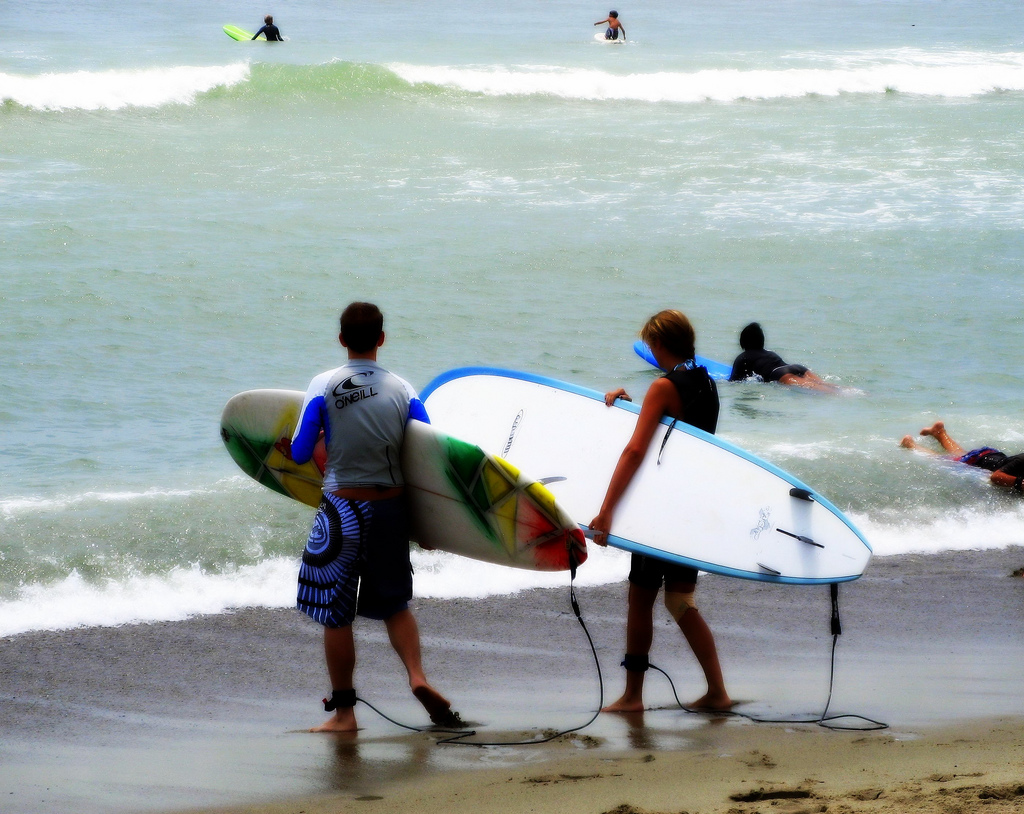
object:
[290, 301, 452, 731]
boy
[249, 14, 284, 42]
surfer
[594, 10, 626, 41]
boy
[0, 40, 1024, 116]
waves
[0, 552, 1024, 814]
sand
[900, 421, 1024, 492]
child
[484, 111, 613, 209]
water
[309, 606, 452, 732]
legs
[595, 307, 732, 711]
person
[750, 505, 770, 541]
steamer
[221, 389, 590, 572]
boat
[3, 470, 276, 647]
water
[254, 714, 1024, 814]
mud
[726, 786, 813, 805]
marks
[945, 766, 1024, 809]
marks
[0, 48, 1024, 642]
wavy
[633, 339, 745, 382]
surfboard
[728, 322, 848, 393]
person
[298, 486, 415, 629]
shorts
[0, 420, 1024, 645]
wave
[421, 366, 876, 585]
surfboard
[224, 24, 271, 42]
surfboard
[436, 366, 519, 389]
trim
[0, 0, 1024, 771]
water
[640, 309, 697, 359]
hair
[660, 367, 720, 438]
shirt